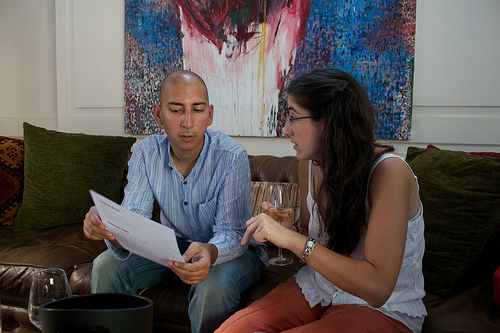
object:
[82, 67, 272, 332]
man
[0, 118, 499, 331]
couch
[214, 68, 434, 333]
woman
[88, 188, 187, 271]
paper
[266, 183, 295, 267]
wine glass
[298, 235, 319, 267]
watch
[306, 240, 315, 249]
face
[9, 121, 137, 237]
throw pillow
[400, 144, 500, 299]
throw pillow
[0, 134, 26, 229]
pillow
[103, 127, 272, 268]
shirt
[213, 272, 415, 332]
pants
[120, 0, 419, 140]
art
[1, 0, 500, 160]
wall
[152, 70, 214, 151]
head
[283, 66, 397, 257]
hair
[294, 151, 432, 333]
tank top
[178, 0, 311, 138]
middle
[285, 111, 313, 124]
glasses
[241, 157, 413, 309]
arm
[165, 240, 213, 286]
hands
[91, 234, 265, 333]
jeans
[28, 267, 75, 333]
wine goblet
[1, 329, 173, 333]
table